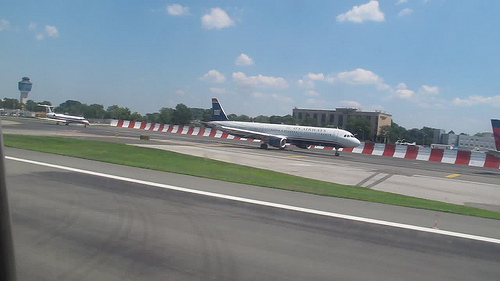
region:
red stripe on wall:
[482, 153, 499, 169]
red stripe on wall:
[453, 148, 468, 164]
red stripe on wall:
[425, 148, 442, 163]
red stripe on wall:
[403, 142, 420, 159]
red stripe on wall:
[379, 141, 396, 156]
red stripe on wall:
[359, 140, 375, 152]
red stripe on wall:
[341, 143, 355, 152]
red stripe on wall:
[115, 118, 125, 128]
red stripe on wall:
[126, 120, 136, 130]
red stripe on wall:
[138, 121, 147, 128]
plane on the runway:
[198, 94, 373, 154]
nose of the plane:
[355, 141, 362, 149]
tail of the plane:
[210, 95, 225, 122]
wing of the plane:
[221, 127, 291, 145]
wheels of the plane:
[252, 140, 287, 155]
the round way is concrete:
[85, 189, 247, 262]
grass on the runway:
[136, 138, 223, 185]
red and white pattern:
[420, 142, 474, 167]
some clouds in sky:
[305, 45, 393, 108]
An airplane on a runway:
[187, 82, 367, 162]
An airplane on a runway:
[195, 91, 365, 164]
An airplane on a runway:
[187, 87, 364, 163]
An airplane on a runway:
[187, 95, 367, 160]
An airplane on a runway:
[177, 92, 372, 162]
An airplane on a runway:
[180, 91, 363, 161]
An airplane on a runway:
[180, 91, 367, 158]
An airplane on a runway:
[176, 95, 376, 158]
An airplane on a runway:
[190, 88, 370, 162]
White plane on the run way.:
[95, 237, 137, 278]